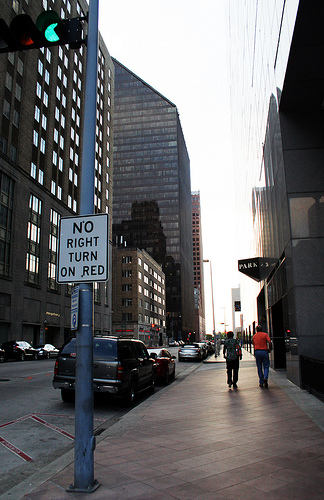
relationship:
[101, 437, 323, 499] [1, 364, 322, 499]
tiles on sidewalk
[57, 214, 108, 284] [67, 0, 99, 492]
sign on pole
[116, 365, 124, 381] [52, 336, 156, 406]
light on car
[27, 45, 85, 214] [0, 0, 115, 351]
windows in building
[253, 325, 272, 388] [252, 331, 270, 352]
man wearing shirt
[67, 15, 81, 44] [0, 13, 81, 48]
bolts securing signal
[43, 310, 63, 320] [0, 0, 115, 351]
writing in front of building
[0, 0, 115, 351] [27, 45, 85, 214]
building covered with windows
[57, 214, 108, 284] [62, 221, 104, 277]
sign with letters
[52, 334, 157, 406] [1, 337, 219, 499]
car on road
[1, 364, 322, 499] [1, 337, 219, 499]
sidewalk by road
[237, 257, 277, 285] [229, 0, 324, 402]
sign on building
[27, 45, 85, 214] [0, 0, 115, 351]
windows on building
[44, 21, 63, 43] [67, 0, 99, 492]
light on pole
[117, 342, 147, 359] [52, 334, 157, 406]
window on car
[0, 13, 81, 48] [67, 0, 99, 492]
signal on pole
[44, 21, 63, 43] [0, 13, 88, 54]
light on signal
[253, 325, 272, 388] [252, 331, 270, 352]
man in shirt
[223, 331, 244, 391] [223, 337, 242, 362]
man in shirt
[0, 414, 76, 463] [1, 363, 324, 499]
stripes on sidewalk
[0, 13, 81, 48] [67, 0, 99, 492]
signal on post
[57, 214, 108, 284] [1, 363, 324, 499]
sign on sidewalk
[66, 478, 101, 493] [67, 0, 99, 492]
bolts holding pole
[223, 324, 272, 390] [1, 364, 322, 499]
couple on sidewalk